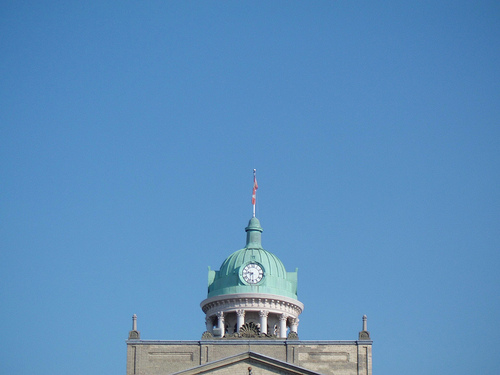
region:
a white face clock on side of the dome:
[240, 260, 265, 281]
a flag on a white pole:
[246, 165, 256, 215]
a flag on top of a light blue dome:
[245, 165, 255, 211]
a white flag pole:
[250, 205, 256, 216]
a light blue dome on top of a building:
[205, 165, 298, 292]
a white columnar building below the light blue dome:
[200, 294, 303, 338]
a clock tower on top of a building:
[198, 166, 305, 338]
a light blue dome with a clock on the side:
[200, 166, 305, 340]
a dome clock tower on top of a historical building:
[124, 166, 374, 373]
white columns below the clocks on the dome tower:
[204, 308, 299, 333]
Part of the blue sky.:
[84, 56, 166, 118]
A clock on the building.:
[239, 262, 266, 285]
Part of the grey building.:
[126, 313, 374, 373]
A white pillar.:
[261, 308, 268, 334]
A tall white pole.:
[252, 164, 258, 217]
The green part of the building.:
[203, 215, 299, 300]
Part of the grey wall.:
[139, 350, 195, 363]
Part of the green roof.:
[231, 250, 263, 255]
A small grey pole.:
[361, 314, 368, 333]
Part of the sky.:
[346, 158, 456, 194]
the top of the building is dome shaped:
[167, 160, 321, 336]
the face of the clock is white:
[232, 257, 275, 286]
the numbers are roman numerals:
[237, 259, 262, 279]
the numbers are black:
[229, 255, 269, 282]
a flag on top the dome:
[230, 160, 277, 228]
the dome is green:
[185, 222, 307, 294]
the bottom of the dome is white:
[177, 288, 309, 340]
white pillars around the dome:
[200, 307, 300, 333]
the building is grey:
[100, 330, 377, 370]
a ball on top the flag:
[247, 159, 267, 176]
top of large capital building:
[91, 196, 385, 371]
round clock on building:
[233, 255, 270, 288]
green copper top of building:
[208, 223, 314, 289]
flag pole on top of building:
[231, 148, 276, 212]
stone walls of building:
[95, 293, 382, 374]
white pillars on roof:
[206, 307, 250, 334]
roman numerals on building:
[238, 255, 292, 292]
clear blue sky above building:
[14, 21, 494, 356]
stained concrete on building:
[151, 335, 368, 373]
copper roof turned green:
[214, 231, 310, 308]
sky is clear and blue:
[9, 18, 460, 172]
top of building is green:
[208, 215, 293, 295]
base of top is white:
[198, 301, 296, 338]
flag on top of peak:
[250, 163, 261, 218]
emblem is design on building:
[233, 318, 263, 341]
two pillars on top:
[121, 313, 373, 350]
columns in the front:
[202, 309, 299, 329]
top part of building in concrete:
[117, 346, 371, 373]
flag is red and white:
[250, 166, 257, 205]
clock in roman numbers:
[240, 256, 265, 290]